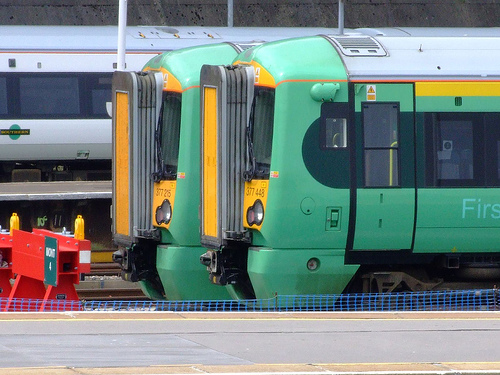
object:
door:
[349, 81, 417, 261]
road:
[0, 308, 500, 374]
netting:
[0, 289, 500, 316]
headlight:
[245, 199, 267, 228]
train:
[108, 32, 500, 311]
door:
[110, 68, 164, 248]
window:
[431, 115, 474, 185]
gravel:
[83, 267, 135, 289]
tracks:
[0, 309, 500, 326]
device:
[1, 211, 96, 319]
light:
[74, 215, 86, 240]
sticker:
[367, 84, 378, 95]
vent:
[327, 30, 388, 58]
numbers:
[246, 185, 266, 198]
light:
[305, 257, 321, 271]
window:
[365, 102, 397, 146]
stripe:
[413, 76, 500, 99]